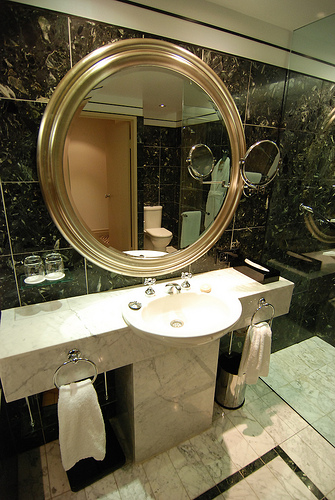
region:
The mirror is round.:
[29, 31, 249, 279]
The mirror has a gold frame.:
[32, 35, 247, 282]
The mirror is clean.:
[26, 37, 267, 279]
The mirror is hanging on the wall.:
[2, 4, 306, 296]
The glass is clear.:
[20, 252, 44, 286]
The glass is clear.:
[42, 250, 71, 286]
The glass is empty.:
[19, 244, 46, 288]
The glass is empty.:
[43, 242, 76, 289]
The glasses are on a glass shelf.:
[11, 248, 90, 310]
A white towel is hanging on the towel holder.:
[49, 344, 114, 474]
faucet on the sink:
[181, 271, 198, 289]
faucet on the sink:
[141, 276, 153, 293]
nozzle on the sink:
[163, 279, 185, 296]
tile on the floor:
[263, 412, 304, 438]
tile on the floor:
[205, 427, 252, 465]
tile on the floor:
[191, 451, 222, 476]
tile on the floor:
[267, 468, 297, 490]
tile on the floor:
[140, 469, 176, 498]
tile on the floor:
[292, 425, 323, 453]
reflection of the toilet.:
[150, 226, 167, 239]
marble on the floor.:
[197, 453, 218, 471]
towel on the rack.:
[80, 403, 90, 443]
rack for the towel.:
[62, 348, 90, 367]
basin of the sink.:
[188, 307, 209, 315]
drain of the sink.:
[168, 316, 182, 330]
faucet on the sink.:
[162, 280, 180, 298]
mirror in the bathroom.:
[249, 143, 279, 179]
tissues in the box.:
[250, 256, 269, 280]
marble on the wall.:
[16, 30, 39, 57]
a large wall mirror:
[33, 34, 249, 281]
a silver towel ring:
[49, 357, 98, 390]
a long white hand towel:
[57, 381, 107, 470]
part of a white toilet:
[142, 205, 172, 251]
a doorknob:
[101, 193, 111, 199]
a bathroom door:
[103, 123, 136, 248]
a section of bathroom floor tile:
[40, 386, 333, 498]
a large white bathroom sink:
[121, 288, 247, 345]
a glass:
[23, 253, 46, 283]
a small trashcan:
[216, 354, 245, 408]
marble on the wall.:
[9, 37, 33, 62]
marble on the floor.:
[191, 452, 227, 475]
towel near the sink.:
[77, 406, 92, 436]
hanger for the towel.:
[59, 350, 90, 376]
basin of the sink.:
[201, 310, 219, 319]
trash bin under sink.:
[225, 368, 240, 404]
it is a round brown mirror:
[34, 35, 250, 276]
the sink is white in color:
[123, 270, 245, 353]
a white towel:
[51, 379, 111, 466]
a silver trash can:
[214, 351, 246, 418]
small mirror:
[240, 139, 293, 191]